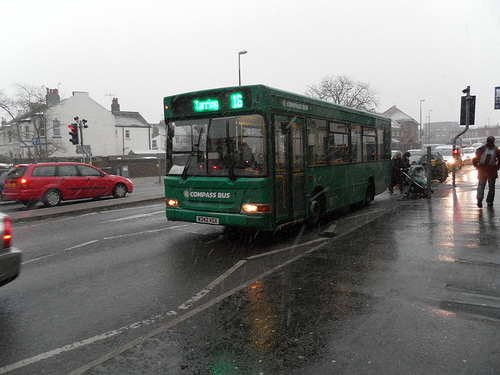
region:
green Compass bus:
[161, 80, 428, 233]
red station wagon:
[8, 160, 138, 210]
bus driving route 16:
[145, 81, 295, 247]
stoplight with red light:
[56, 105, 108, 160]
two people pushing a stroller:
[390, 140, 442, 205]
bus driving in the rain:
[142, 60, 408, 275]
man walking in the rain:
[466, 130, 496, 242]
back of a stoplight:
[450, 86, 483, 156]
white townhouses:
[2, 87, 137, 168]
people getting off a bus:
[381, 139, 460, 225]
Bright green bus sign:
[185, 88, 255, 119]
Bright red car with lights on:
[6, 158, 141, 203]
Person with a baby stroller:
[395, 147, 440, 204]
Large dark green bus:
[153, 79, 408, 233]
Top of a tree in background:
[318, 76, 385, 119]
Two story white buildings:
[7, 82, 169, 159]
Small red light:
[450, 144, 462, 161]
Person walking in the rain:
[472, 129, 498, 216]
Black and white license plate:
[192, 208, 238, 233]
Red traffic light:
[63, 115, 82, 150]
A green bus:
[181, 78, 300, 258]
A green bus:
[204, 104, 332, 334]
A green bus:
[213, 93, 281, 294]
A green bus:
[198, 98, 264, 219]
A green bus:
[222, 160, 304, 306]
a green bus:
[155, 84, 405, 230]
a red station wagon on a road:
[10, 152, 137, 210]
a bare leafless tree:
[313, 70, 384, 115]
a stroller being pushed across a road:
[392, 153, 429, 198]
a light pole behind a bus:
[231, 44, 255, 87]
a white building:
[8, 94, 161, 160]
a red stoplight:
[67, 121, 85, 149]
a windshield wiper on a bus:
[171, 121, 208, 186]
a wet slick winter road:
[8, 152, 449, 371]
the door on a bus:
[266, 109, 314, 222]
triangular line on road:
[200, 249, 344, 307]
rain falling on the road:
[169, 220, 331, 295]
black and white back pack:
[472, 142, 499, 173]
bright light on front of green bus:
[229, 193, 281, 218]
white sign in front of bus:
[155, 163, 198, 183]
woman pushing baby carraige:
[394, 146, 443, 206]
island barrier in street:
[17, 185, 157, 214]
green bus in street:
[150, 75, 410, 225]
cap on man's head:
[482, 125, 497, 143]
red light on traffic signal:
[50, 106, 111, 176]